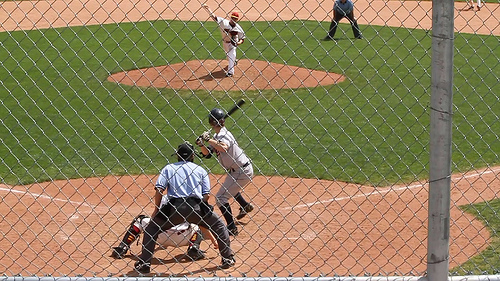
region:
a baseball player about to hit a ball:
[195, 98, 253, 235]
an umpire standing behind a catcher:
[136, 139, 237, 271]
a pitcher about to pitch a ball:
[200, 3, 246, 73]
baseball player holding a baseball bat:
[192, 97, 245, 147]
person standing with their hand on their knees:
[323, 2, 363, 44]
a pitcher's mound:
[104, 60, 345, 89]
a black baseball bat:
[191, 97, 246, 145]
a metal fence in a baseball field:
[1, 1, 498, 279]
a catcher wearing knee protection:
[124, 210, 146, 250]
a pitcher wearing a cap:
[227, 10, 242, 19]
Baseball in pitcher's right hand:
[200, 1, 210, 9]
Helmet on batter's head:
[207, 108, 226, 125]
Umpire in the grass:
[322, 0, 369, 43]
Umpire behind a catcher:
[136, 141, 238, 271]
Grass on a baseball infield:
[0, 16, 494, 190]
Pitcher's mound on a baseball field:
[103, 53, 353, 88]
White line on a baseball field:
[271, 154, 498, 214]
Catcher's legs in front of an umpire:
[111, 211, 220, 261]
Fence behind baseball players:
[1, 0, 498, 279]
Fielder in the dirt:
[468, 0, 484, 13]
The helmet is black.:
[205, 105, 227, 125]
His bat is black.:
[197, 99, 244, 137]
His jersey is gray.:
[200, 125, 257, 233]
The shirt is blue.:
[150, 159, 214, 201]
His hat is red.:
[225, 11, 245, 20]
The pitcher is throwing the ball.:
[193, 2, 255, 77]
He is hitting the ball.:
[180, 95, 290, 240]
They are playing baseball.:
[16, 7, 389, 273]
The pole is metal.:
[432, 4, 464, 275]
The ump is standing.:
[134, 134, 246, 276]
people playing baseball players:
[87, 50, 374, 280]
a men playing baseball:
[75, 36, 276, 258]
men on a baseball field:
[79, 11, 345, 268]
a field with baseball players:
[30, 2, 436, 277]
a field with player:
[61, 2, 466, 279]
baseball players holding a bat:
[148, 81, 286, 232]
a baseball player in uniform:
[139, 89, 290, 268]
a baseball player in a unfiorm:
[207, 64, 307, 232]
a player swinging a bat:
[178, 51, 298, 256]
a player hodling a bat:
[168, 87, 305, 248]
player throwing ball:
[193, 4, 246, 76]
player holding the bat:
[197, 94, 284, 231]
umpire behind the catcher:
[131, 141, 233, 271]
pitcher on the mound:
[191, 0, 256, 89]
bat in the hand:
[215, 89, 259, 133]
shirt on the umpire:
[162, 158, 212, 202]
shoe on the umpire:
[123, 257, 157, 272]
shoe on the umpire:
[221, 253, 238, 269]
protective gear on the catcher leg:
[112, 217, 139, 256]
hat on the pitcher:
[228, 11, 243, 20]